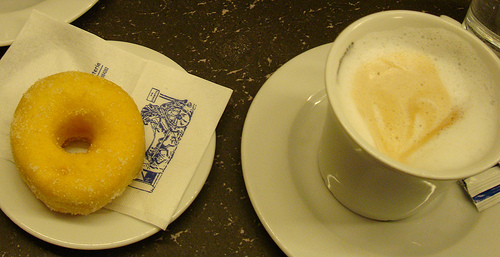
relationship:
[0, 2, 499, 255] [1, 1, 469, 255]
table has spots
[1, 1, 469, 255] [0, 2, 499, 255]
spots are on table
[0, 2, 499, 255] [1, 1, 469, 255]
table contains spots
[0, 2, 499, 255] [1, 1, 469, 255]
table covered with spots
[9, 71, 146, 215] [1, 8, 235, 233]
donut on napkin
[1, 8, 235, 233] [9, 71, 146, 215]
napkin beneath donut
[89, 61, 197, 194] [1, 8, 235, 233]
drawing on napkin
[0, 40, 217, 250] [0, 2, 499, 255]
plate on table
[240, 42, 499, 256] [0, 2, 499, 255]
plate on table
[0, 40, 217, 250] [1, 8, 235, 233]
plate beneath napkin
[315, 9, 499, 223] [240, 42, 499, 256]
mug on top of plate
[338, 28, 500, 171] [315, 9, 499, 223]
coffee inside of mug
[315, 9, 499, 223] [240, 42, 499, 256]
mug on plate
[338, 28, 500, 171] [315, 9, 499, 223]
coffee in mug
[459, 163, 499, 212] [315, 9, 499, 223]
bag near mug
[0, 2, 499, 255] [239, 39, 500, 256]
table beneath plate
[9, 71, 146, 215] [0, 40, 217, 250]
donut resting on plate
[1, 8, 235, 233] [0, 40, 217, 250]
napkin top of plate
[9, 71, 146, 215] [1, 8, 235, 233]
donut sitting on top of napkin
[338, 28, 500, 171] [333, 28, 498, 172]
coffee has foam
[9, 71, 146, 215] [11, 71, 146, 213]
donut has sugar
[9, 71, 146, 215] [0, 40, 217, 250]
donut sitting on plate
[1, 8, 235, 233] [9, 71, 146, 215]
napkin underneath donut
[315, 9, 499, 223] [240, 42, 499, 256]
mug resting on plate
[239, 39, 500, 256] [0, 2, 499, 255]
plate are on table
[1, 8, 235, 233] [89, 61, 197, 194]
napkin has drawing